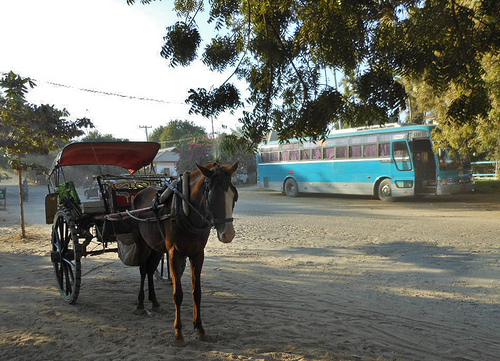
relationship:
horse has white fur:
[130, 162, 238, 346] [218, 187, 236, 237]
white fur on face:
[218, 187, 236, 237] [195, 162, 238, 244]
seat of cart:
[98, 171, 169, 212] [45, 141, 179, 304]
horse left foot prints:
[122, 164, 242, 349] [221, 278, 368, 328]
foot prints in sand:
[221, 278, 368, 328] [9, 197, 499, 359]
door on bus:
[390, 138, 415, 198] [256, 121, 476, 201]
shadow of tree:
[1, 247, 498, 359] [161, 2, 498, 159]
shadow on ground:
[1, 247, 498, 359] [1, 175, 498, 360]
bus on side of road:
[256, 122, 476, 203] [188, 185, 498, 234]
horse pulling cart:
[122, 164, 242, 349] [44, 136, 156, 311]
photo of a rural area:
[225, 110, 421, 283] [3, 7, 498, 354]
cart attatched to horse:
[45, 141, 179, 304] [122, 164, 242, 349]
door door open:
[390, 138, 415, 198] [356, 162, 416, 263]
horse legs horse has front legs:
[168, 247, 186, 347] [125, 263, 236, 361]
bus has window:
[256, 121, 476, 201] [287, 150, 300, 160]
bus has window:
[256, 121, 476, 201] [394, 142, 409, 157]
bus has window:
[256, 121, 476, 201] [362, 142, 378, 156]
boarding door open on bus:
[358, 112, 434, 203] [244, 119, 472, 209]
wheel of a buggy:
[46, 207, 82, 307] [34, 202, 87, 345]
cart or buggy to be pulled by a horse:
[42, 134, 174, 301] [130, 162, 238, 346]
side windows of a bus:
[352, 118, 381, 178] [256, 121, 476, 201]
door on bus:
[390, 138, 415, 198] [246, 116, 488, 210]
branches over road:
[239, 74, 381, 150] [279, 200, 429, 252]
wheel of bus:
[275, 161, 301, 212] [243, 95, 483, 237]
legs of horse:
[134, 254, 212, 349] [117, 151, 247, 347]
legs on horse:
[164, 257, 219, 348] [121, 157, 273, 345]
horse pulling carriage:
[130, 162, 238, 346] [25, 102, 290, 332]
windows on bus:
[259, 144, 401, 162] [248, 130, 471, 205]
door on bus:
[390, 138, 415, 198] [231, 105, 484, 237]